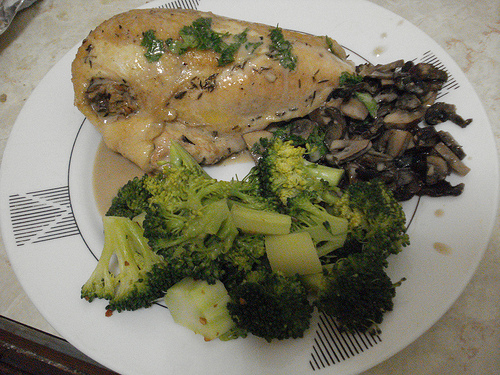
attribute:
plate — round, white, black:
[2, 0, 498, 375]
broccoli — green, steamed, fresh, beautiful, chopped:
[78, 137, 411, 344]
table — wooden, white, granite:
[2, 0, 499, 375]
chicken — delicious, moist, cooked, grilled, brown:
[68, 8, 358, 172]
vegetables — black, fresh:
[139, 23, 313, 74]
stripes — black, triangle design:
[4, 184, 81, 249]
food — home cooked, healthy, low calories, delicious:
[71, 9, 472, 343]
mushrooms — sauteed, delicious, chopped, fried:
[277, 52, 477, 208]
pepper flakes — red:
[96, 247, 221, 344]